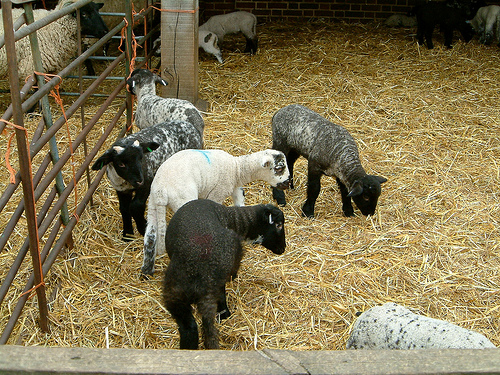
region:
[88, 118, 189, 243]
a black and white goat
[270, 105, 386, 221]
a black and white goat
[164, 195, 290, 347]
a black and white goat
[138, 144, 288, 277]
a white goat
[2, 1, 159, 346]
a rusted metal fence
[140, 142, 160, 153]
ear of a sheep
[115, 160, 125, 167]
eye of a sheep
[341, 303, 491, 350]
a black spotted sheep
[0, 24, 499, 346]
a bed of hay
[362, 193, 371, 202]
eye of a sheep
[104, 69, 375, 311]
a bunch of baby goats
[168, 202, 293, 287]
a small black baby goat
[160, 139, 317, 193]
a small white baby goat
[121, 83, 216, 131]
a small grey and white baby goat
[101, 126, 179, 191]
a small black and white baby goat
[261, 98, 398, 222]
a small grey baby goat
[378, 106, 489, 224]
a bunch of yellow hay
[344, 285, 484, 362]
a small white spotted baby goat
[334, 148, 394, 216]
the head of a baby goat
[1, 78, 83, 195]
a rusted steel metal fence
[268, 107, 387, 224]
sheep is gray and black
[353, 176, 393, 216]
sheep's face is black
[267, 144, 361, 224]
sheep's legs are black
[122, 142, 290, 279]
the sheep is white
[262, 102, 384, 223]
the sheep is eating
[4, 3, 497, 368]
sheep are standing on straw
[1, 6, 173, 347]
metal railing behind the sheep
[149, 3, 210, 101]
wooden post behind the sheep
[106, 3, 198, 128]
orange string tied around post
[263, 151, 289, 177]
black spots on sheep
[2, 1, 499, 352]
Herd of sheep in pens.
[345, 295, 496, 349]
black dotted sheep in the front.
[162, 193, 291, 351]
Black sheep in the front.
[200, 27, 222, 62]
Black spot on sheep.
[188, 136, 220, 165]
Blue mark on the sheep.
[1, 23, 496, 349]
hay covering the ground.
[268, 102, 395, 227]
Sheep eating the hay.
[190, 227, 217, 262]
Red spot on black sheep.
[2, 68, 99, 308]
Orange rope on the fence.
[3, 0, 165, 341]
Fence diving the pen.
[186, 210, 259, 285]
black sheared small sheep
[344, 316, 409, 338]
black and white sheep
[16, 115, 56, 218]
metal railing on sheep's pen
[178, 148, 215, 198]
white sheep with black face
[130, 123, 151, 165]
gray and black sheep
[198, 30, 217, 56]
small white sheep in background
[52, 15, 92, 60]
white sheep with dirty wool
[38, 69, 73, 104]
orange string on railing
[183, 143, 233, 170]
blue mark on sheeps back